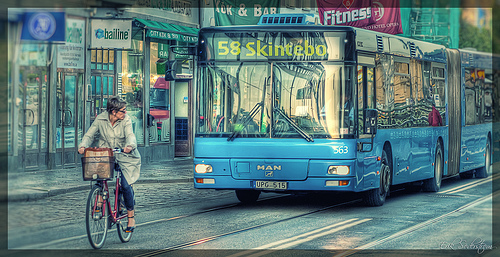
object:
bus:
[190, 25, 497, 208]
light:
[194, 163, 212, 174]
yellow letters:
[212, 41, 329, 58]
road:
[9, 177, 498, 253]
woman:
[83, 99, 143, 231]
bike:
[74, 147, 135, 247]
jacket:
[77, 111, 143, 185]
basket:
[79, 155, 114, 178]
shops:
[7, 10, 196, 163]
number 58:
[214, 40, 237, 56]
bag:
[83, 146, 111, 179]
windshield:
[194, 68, 353, 138]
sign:
[88, 24, 132, 44]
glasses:
[114, 110, 128, 114]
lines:
[247, 217, 360, 247]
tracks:
[166, 201, 235, 243]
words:
[240, 39, 327, 57]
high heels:
[124, 216, 136, 235]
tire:
[366, 149, 391, 204]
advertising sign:
[318, 7, 402, 31]